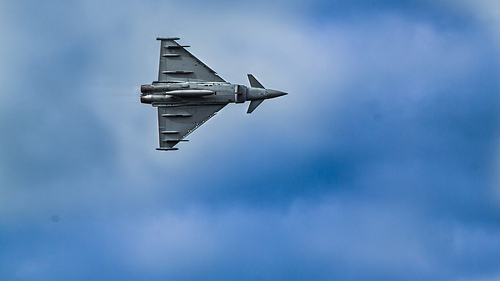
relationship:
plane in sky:
[140, 35, 290, 157] [1, 1, 499, 279]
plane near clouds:
[140, 35, 290, 157] [106, 18, 335, 166]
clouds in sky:
[106, 18, 335, 166] [1, 1, 499, 279]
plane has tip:
[140, 35, 290, 157] [263, 85, 290, 103]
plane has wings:
[140, 35, 290, 157] [155, 35, 232, 153]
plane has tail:
[140, 35, 290, 157] [138, 80, 162, 112]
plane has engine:
[140, 35, 290, 157] [142, 83, 188, 104]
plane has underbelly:
[140, 35, 290, 157] [156, 50, 239, 136]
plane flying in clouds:
[140, 35, 290, 157] [106, 18, 335, 166]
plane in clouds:
[140, 35, 290, 157] [106, 18, 335, 166]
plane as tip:
[140, 35, 290, 157] [263, 85, 290, 103]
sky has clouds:
[1, 1, 499, 279] [106, 18, 335, 166]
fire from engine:
[88, 83, 145, 104] [142, 83, 188, 104]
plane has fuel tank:
[140, 35, 290, 157] [139, 80, 193, 92]